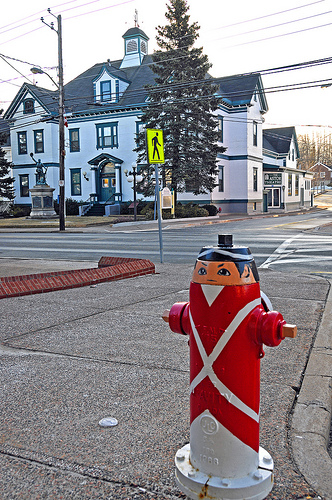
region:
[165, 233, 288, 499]
the fire hydrant looks like an anime character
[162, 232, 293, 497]
the fire hydrant is painted red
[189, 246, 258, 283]
the fire hydrant has a face painted on it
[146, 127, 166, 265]
the sign has a man on it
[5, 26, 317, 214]
the house is green and white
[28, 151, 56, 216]
the statue is holding something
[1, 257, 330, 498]
the side walk is made of cement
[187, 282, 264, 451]
the fire hydrant has an x on it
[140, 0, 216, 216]
a large tree is in front of the building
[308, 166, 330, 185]
a brown and white house is in the background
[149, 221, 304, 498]
Red and white painted fire hydrant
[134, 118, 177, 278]
Yellow sign with metal pole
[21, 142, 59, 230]
Metal statue with concrete base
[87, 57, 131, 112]
White and green house window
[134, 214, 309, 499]
Fire hydrant with face painted on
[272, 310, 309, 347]
Large fire hydrant nut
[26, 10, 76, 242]
Wooden telephone pole with light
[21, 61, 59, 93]
Metal and glass street light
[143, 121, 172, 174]
Yellow sign with person painted on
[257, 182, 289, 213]
Glass door on house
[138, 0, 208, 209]
A large tree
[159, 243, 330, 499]
A fire hydrant near the curb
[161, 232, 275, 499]
A fire hydrant painted like an asian cartoon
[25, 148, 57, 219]
A stone statue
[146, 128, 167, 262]
A neon crosswalk sign on a metal pole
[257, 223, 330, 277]
The crosswalk section of the road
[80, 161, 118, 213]
Front doors and steps of the big building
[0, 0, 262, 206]
A large white building with dark blue trim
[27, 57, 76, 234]
A wooden electric pole and street light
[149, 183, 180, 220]
The white and yellow wooden sign for the big building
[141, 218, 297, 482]
A decorated fire hydrant.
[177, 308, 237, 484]
Writing on the fire hydrant.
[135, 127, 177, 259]
A street sign.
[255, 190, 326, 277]
A crosswalk.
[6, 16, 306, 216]
A large white and green building.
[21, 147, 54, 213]
A statue.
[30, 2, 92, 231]
A utility pole attached to many power lines.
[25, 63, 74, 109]
A streetlight attached to the utility pole.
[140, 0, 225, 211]
A large pine tree.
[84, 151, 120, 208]
The entrance to the building.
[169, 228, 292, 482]
fire hydrant painted as soldier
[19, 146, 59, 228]
statue in front of building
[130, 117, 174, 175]
yellow crosswalk street sign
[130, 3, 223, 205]
tree in front of building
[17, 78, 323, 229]
blue and white building on corner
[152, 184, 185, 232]
sign in front of building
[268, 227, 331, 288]
white lines painted on street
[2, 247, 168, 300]
short red brick wall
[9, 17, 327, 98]
multiple utility lines above street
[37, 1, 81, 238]
utility pole on street corner